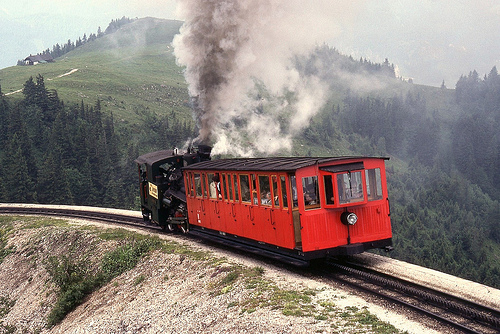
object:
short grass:
[0, 299, 27, 332]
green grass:
[45, 49, 166, 77]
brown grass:
[0, 214, 90, 327]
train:
[135, 146, 395, 267]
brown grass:
[91, 242, 146, 278]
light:
[341, 211, 360, 226]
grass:
[81, 66, 169, 106]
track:
[0, 190, 499, 330]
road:
[7, 52, 164, 96]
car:
[136, 147, 397, 271]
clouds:
[22, 20, 54, 37]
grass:
[157, 252, 385, 333]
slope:
[1, 211, 466, 333]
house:
[24, 54, 53, 66]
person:
[304, 192, 314, 206]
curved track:
[3, 201, 144, 233]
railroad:
[1, 201, 499, 332]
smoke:
[174, 0, 349, 156]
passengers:
[208, 175, 223, 197]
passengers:
[256, 183, 318, 208]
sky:
[0, 0, 493, 51]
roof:
[180, 155, 391, 173]